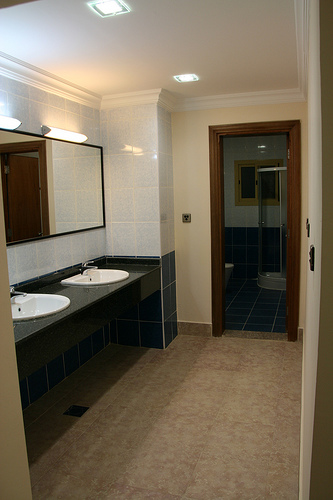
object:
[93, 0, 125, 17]
light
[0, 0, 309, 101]
ceiling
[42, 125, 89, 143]
light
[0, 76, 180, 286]
wall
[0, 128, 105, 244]
mirror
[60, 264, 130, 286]
sink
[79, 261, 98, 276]
faucet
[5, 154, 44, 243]
door reflection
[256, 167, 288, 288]
shower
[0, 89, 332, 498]
bathroom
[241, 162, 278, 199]
window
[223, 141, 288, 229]
wall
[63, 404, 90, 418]
drain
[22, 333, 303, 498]
floor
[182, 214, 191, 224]
plug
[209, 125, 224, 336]
door frame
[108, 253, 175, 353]
tiles on wall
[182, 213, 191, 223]
light switch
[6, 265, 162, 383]
counter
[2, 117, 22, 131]
light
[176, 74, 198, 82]
light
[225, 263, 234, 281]
toilet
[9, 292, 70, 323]
sink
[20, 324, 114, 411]
tile under counter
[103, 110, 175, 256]
tile next to mirror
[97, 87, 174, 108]
crown molding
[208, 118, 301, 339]
doorway